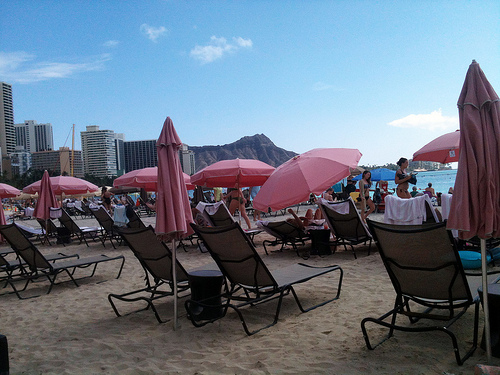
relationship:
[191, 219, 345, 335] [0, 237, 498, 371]
lounge chair sitting on top of sand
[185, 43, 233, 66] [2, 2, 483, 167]
cloud hanging in sky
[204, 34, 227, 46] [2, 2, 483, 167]
cloud hanging in sky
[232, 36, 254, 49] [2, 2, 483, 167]
cloud hanging in sky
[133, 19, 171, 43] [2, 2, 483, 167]
cloud hanging in sky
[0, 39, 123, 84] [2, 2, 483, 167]
cloud hanging in sky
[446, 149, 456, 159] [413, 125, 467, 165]
number tag on umbrella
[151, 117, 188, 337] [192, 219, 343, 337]
umbrella next chair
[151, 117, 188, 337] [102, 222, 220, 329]
umbrella next chair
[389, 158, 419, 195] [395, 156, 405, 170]
woman has hair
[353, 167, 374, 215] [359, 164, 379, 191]
woman has hair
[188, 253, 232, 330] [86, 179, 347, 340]
container between chairs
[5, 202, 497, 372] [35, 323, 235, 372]
sand on ground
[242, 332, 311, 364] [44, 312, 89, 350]
foot prints on sand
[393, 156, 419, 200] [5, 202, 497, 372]
woman on sand